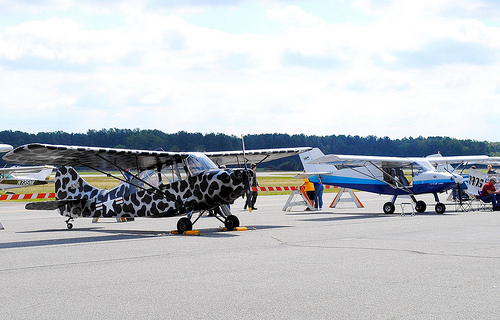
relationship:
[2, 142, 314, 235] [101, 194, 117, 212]
airplane has star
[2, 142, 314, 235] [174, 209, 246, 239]
airplane has black wheels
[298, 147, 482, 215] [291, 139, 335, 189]
airplane has tail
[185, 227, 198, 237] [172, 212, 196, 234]
chocks block wheel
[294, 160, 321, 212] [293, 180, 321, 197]
person has shirt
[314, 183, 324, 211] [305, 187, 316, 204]
people has shorts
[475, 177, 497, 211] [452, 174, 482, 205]
man has shirt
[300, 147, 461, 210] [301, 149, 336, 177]
airplane has tail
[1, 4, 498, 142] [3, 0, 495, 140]
clouds in sky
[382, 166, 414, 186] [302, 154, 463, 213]
door on airplane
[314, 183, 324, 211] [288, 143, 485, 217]
people standing behind airplane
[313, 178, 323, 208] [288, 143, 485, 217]
people standing behind airplane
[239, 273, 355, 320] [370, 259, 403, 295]
part of a floor